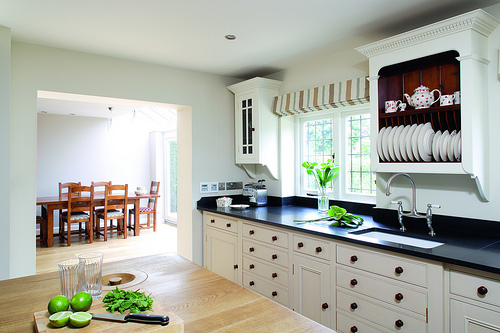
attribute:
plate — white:
[418, 122, 436, 162]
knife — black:
[87, 311, 171, 327]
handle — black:
[123, 310, 171, 326]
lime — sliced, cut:
[48, 310, 94, 329]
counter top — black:
[194, 200, 499, 276]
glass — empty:
[59, 257, 84, 303]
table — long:
[36, 190, 162, 247]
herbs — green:
[103, 288, 154, 317]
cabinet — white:
[201, 8, 499, 332]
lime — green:
[70, 290, 94, 311]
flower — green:
[303, 153, 341, 190]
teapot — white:
[404, 84, 442, 112]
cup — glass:
[79, 252, 104, 298]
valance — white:
[271, 76, 371, 118]